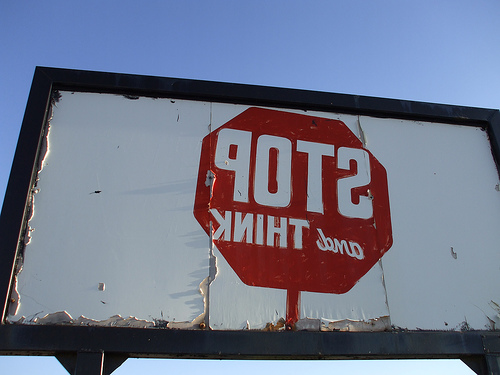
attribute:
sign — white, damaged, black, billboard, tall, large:
[0, 64, 499, 374]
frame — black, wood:
[3, 64, 499, 374]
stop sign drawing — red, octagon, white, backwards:
[192, 109, 394, 331]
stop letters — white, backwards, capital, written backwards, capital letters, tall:
[214, 129, 375, 220]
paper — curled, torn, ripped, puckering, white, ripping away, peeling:
[6, 86, 499, 342]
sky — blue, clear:
[2, 4, 495, 374]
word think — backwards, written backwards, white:
[208, 207, 309, 251]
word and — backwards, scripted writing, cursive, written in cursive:
[315, 226, 365, 261]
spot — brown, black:
[265, 315, 286, 330]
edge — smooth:
[338, 116, 383, 171]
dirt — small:
[93, 187, 104, 197]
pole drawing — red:
[286, 288, 303, 329]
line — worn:
[203, 103, 220, 329]